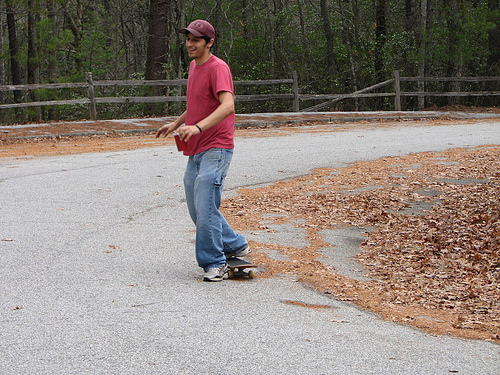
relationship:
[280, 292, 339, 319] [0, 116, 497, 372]
spot on ground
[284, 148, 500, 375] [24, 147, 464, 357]
spot on sidewalk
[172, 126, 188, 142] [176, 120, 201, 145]
cigarette in hand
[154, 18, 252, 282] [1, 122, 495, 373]
man skating on street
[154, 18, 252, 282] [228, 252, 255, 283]
man riding skateboard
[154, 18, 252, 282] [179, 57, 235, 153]
man wearing shirt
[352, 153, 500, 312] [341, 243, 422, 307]
brown leaves on ground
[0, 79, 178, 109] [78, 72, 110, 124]
fence with post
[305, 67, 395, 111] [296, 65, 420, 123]
piece of fence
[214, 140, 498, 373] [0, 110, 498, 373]
curve in pavement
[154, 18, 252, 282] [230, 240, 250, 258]
man with foot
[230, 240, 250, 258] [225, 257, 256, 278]
foot on skateboard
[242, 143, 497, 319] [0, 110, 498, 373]
leaves on pavement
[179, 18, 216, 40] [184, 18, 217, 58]
hat on head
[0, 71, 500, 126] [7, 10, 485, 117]
fence in background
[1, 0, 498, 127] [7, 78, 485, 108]
trees behind fence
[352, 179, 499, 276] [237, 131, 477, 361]
brown leaves on ground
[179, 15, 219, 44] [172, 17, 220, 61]
cap on head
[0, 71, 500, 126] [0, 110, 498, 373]
fence along side of pavement